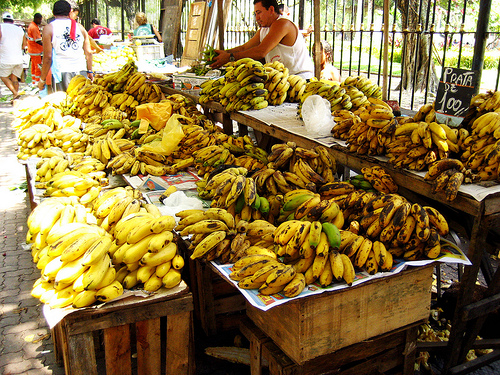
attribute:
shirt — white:
[1, 21, 25, 66]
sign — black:
[434, 65, 475, 129]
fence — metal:
[177, 0, 498, 112]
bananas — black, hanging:
[419, 157, 478, 207]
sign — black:
[54, 49, 96, 80]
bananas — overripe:
[176, 132, 448, 294]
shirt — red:
[87, 23, 113, 38]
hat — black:
[89, 17, 107, 27]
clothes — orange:
[27, 22, 41, 81]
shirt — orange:
[248, 17, 342, 79]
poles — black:
[316, 3, 474, 66]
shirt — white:
[321, 58, 342, 85]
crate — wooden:
[228, 261, 440, 363]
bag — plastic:
[297, 90, 334, 140]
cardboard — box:
[176, 69, 221, 89]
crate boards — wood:
[53, 289, 193, 373]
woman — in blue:
[128, 4, 157, 49]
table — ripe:
[20, 151, 200, 373]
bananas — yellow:
[19, 98, 176, 302]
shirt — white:
[250, 24, 336, 84]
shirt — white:
[257, 17, 317, 85]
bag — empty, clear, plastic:
[301, 93, 337, 136]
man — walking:
[0, 12, 27, 102]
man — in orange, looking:
[21, 10, 49, 84]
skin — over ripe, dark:
[366, 192, 410, 211]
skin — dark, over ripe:
[377, 199, 407, 227]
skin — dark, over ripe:
[390, 201, 412, 226]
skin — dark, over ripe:
[419, 204, 449, 235]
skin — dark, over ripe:
[395, 213, 416, 244]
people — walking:
[1, 7, 31, 102]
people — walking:
[24, 9, 49, 90]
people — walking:
[42, 0, 92, 92]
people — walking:
[82, 16, 112, 38]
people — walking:
[133, 10, 162, 42]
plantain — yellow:
[160, 267, 180, 288]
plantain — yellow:
[142, 271, 164, 292]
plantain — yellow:
[170, 254, 184, 269]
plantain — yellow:
[138, 241, 176, 268]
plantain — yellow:
[146, 230, 173, 254]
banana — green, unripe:
[260, 210, 340, 259]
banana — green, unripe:
[106, 197, 177, 271]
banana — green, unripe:
[389, 110, 449, 166]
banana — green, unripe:
[147, 110, 204, 167]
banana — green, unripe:
[217, 50, 278, 104]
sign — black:
[420, 52, 492, 133]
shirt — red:
[21, 24, 78, 84]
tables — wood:
[188, 192, 440, 345]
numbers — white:
[442, 56, 468, 121]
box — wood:
[228, 265, 435, 339]